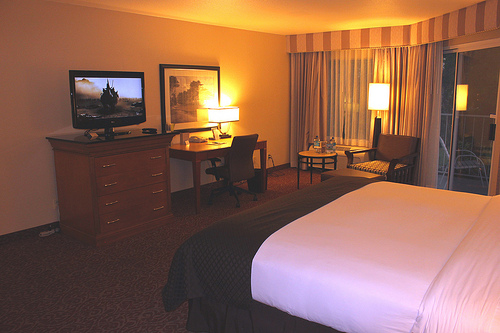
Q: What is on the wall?
A: Picture.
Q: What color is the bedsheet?
A: White.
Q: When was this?
A: Nightime.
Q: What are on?
A: Lights.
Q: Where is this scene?
A: Bedroom.